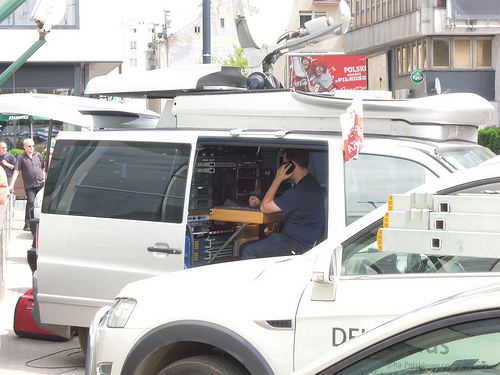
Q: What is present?
A: Cars.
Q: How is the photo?
A: Clear.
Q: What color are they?
A: White.